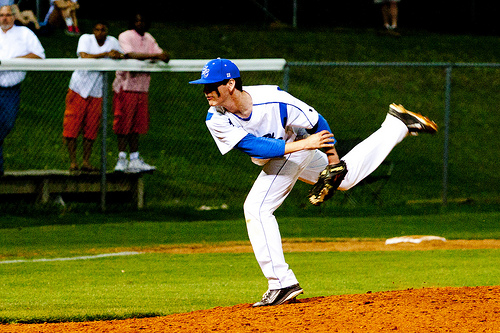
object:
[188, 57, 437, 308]
pitcher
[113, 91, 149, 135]
shorts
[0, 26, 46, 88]
shirt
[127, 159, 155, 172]
shoe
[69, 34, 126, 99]
shirt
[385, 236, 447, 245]
base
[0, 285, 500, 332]
mound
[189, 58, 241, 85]
cap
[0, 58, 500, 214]
fence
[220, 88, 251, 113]
neck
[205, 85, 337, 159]
shirt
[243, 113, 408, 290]
pants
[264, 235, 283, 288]
stripe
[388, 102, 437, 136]
shoe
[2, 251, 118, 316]
grass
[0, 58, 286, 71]
padding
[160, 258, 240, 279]
part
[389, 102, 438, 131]
edge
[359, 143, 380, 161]
part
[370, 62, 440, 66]
part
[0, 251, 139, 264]
line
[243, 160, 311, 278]
leg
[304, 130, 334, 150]
hand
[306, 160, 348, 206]
glove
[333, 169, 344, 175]
part